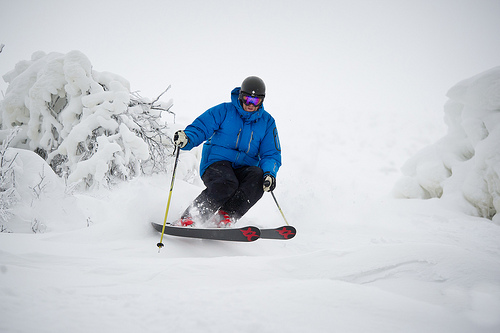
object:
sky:
[0, 0, 500, 168]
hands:
[169, 131, 280, 189]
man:
[170, 74, 289, 237]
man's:
[156, 75, 309, 248]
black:
[241, 75, 267, 96]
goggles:
[242, 89, 263, 106]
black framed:
[239, 95, 264, 105]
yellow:
[155, 175, 175, 256]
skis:
[148, 220, 303, 250]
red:
[240, 227, 263, 239]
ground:
[0, 191, 499, 330]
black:
[150, 220, 255, 240]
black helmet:
[240, 76, 266, 98]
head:
[243, 75, 269, 111]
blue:
[186, 88, 284, 177]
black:
[181, 162, 267, 226]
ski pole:
[145, 141, 183, 255]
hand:
[171, 130, 191, 145]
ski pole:
[265, 180, 289, 227]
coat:
[174, 98, 286, 172]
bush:
[1, 41, 184, 234]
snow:
[0, 0, 499, 333]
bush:
[393, 68, 496, 226]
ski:
[139, 224, 296, 239]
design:
[240, 224, 259, 237]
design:
[276, 221, 294, 239]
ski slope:
[0, 161, 499, 330]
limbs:
[154, 128, 294, 247]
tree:
[0, 44, 185, 195]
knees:
[208, 164, 269, 201]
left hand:
[257, 173, 278, 190]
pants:
[187, 154, 268, 246]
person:
[157, 75, 292, 242]